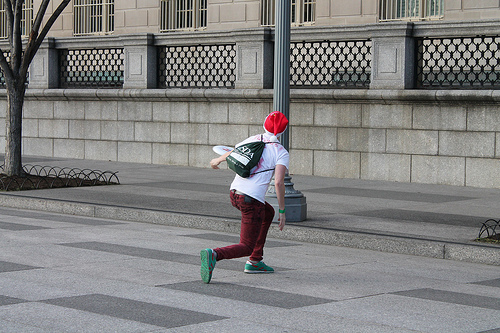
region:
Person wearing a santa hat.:
[177, 71, 344, 328]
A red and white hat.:
[255, 105, 292, 141]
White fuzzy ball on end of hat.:
[268, 132, 282, 145]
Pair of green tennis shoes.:
[185, 239, 280, 290]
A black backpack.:
[221, 130, 283, 182]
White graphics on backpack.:
[224, 130, 266, 183]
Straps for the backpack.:
[250, 121, 287, 177]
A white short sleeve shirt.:
[229, 123, 290, 213]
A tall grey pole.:
[266, 2, 307, 222]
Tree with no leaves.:
[6, 0, 63, 190]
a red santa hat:
[256, 109, 297, 154]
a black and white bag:
[233, 134, 273, 171]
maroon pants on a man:
[197, 184, 295, 276]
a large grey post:
[242, 5, 320, 228]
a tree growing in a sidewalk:
[4, 3, 95, 178]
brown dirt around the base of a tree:
[6, 163, 103, 193]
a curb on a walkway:
[10, 189, 497, 265]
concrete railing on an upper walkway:
[14, 19, 497, 96]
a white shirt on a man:
[225, 130, 287, 202]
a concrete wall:
[2, 87, 497, 181]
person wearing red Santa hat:
[197, 102, 306, 287]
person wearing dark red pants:
[193, 180, 283, 290]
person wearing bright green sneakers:
[196, 235, 287, 289]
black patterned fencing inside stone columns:
[60, 28, 498, 96]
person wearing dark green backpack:
[220, 104, 288, 194]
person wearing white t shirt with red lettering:
[205, 109, 295, 221]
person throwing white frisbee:
[194, 94, 296, 292]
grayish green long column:
[264, 0, 296, 111]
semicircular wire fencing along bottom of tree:
[3, 148, 120, 192]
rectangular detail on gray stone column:
[126, 50, 145, 82]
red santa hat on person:
[258, 102, 285, 141]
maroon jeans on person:
[214, 190, 269, 264]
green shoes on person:
[236, 253, 272, 278]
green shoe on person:
[196, 249, 218, 289]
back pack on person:
[233, 134, 266, 184]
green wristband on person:
[274, 204, 289, 214]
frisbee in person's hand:
[211, 138, 226, 159]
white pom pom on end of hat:
[263, 130, 278, 145]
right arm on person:
[271, 167, 296, 238]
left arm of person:
[205, 152, 230, 173]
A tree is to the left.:
[1, 1, 76, 199]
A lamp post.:
[260, 0, 316, 226]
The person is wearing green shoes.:
[193, 240, 290, 292]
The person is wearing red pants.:
[191, 180, 283, 277]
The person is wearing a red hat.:
[250, 105, 302, 150]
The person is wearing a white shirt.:
[223, 122, 298, 215]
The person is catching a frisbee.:
[201, 139, 243, 169]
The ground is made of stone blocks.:
[21, 237, 160, 325]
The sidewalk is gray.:
[31, 237, 186, 327]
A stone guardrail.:
[313, 17, 497, 97]